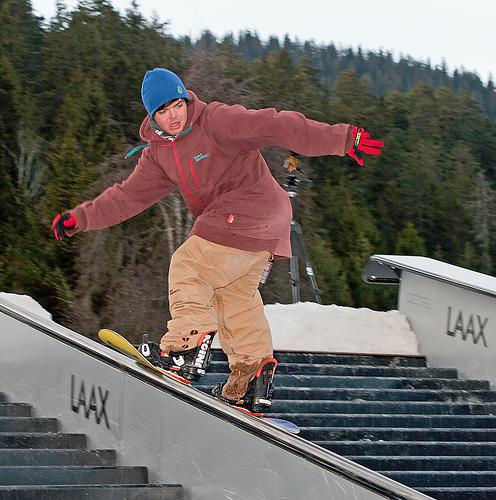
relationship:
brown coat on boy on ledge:
[73, 109, 368, 254] [82, 334, 318, 498]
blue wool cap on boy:
[128, 60, 204, 117] [101, 36, 364, 381]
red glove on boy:
[35, 209, 87, 249] [92, 39, 397, 405]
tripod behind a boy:
[202, 134, 361, 334] [53, 67, 383, 402]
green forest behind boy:
[2, 23, 494, 269] [53, 67, 383, 402]